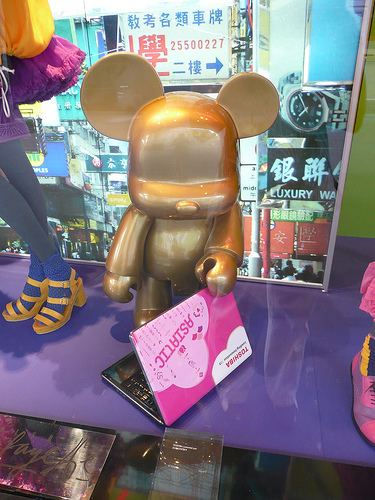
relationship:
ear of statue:
[77, 51, 163, 142] [79, 51, 279, 337]